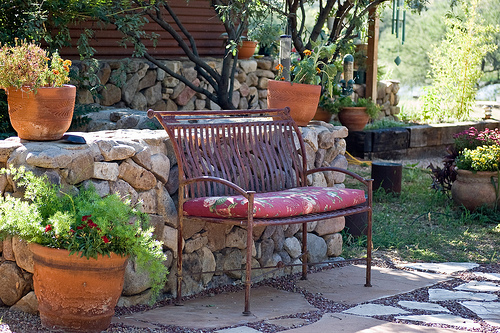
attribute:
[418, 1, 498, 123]
tree — short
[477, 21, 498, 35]
leaves — light green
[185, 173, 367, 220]
cushion — red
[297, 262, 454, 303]
flat stone — large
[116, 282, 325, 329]
flat stone — large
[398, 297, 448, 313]
flat stone — large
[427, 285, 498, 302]
flat stone — large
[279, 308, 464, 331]
flat stone — large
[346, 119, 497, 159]
wooden fence — short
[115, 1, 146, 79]
leaves — green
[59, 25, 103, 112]
leaves — green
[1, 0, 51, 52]
leaves — green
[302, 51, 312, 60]
flower — yellow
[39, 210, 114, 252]
flowers — red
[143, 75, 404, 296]
bench — red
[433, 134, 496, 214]
plant — green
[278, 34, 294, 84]
birdfeeder — little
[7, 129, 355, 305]
wall — stone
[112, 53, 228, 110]
wall — stone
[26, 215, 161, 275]
flower — red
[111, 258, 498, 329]
walkway — stone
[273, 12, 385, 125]
feeders — hanging, tube-shaped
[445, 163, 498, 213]
planter — clay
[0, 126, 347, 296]
wall — stone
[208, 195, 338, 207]
cushion — floral, red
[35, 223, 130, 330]
planter — green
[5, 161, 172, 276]
plant — feathery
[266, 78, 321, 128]
planter — clay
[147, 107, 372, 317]
bench — flowered, rusted, metal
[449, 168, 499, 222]
planter — stoneware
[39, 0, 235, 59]
wall — wood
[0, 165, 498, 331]
ground — paved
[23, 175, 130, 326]
plants — flowering